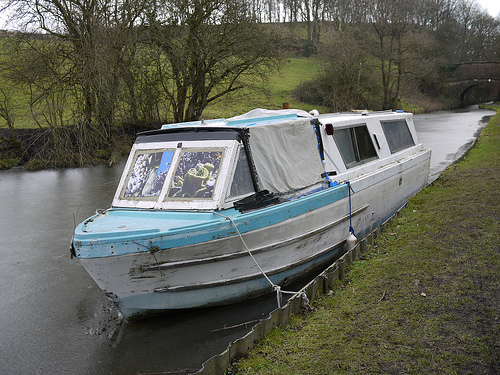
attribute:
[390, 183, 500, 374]
ground — part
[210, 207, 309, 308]
rope — part, white, pictured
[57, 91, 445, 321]
boat — blue, white, pictured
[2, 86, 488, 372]
water — narrow, calm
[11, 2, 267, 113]
trees — pictured, dry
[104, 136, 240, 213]
window — pictured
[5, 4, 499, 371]
light — daytime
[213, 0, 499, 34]
trees — leafless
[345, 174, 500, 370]
grass — green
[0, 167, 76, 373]
river — calm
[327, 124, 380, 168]
window — open